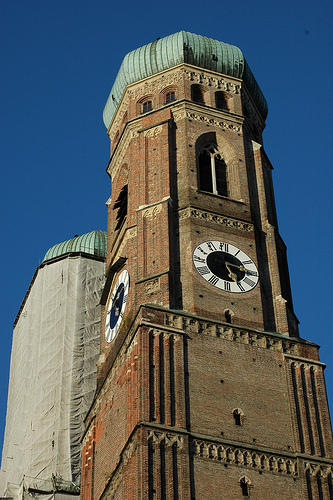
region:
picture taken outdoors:
[31, 211, 331, 429]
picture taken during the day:
[44, 253, 300, 498]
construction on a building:
[28, 214, 97, 483]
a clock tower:
[109, 214, 324, 498]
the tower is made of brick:
[87, 226, 293, 482]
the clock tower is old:
[137, 237, 309, 476]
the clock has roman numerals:
[167, 222, 292, 357]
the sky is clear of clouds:
[24, 195, 130, 261]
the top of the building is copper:
[36, 220, 106, 289]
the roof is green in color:
[31, 217, 111, 262]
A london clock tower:
[108, 22, 288, 386]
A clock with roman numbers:
[190, 240, 262, 296]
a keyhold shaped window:
[219, 398, 264, 432]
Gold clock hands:
[219, 260, 256, 284]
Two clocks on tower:
[81, 235, 268, 342]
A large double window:
[193, 128, 246, 210]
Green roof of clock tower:
[115, 32, 288, 98]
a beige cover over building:
[21, 229, 107, 486]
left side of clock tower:
[132, 122, 172, 214]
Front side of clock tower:
[185, 75, 268, 444]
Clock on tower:
[194, 234, 260, 300]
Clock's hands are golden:
[223, 259, 249, 284]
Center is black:
[210, 251, 243, 279]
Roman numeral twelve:
[218, 239, 228, 252]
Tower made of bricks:
[201, 346, 288, 444]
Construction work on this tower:
[24, 263, 89, 480]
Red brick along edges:
[126, 359, 139, 425]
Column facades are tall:
[142, 330, 184, 427]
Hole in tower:
[231, 406, 248, 427]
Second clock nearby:
[104, 273, 133, 326]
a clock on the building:
[188, 237, 271, 310]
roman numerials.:
[192, 260, 218, 285]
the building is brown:
[140, 314, 284, 461]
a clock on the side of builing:
[100, 292, 130, 335]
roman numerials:
[115, 292, 132, 313]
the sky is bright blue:
[293, 261, 325, 309]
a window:
[199, 153, 233, 198]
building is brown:
[93, 405, 126, 449]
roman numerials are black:
[188, 246, 219, 282]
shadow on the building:
[166, 281, 185, 304]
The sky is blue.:
[287, 68, 327, 169]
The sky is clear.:
[293, 96, 332, 195]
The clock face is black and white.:
[184, 238, 266, 301]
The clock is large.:
[189, 237, 261, 303]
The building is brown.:
[190, 346, 225, 435]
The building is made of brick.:
[186, 337, 225, 442]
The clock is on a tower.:
[93, 122, 314, 352]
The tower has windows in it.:
[176, 123, 252, 219]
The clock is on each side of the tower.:
[95, 240, 274, 343]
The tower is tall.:
[92, 94, 332, 498]